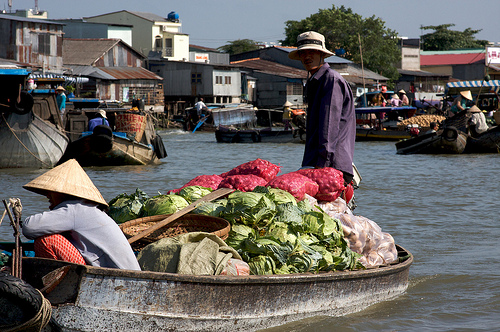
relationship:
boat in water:
[5, 237, 413, 331] [2, 129, 499, 331]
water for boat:
[2, 129, 499, 331] [5, 237, 413, 331]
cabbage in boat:
[228, 192, 271, 226] [5, 237, 413, 331]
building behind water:
[62, 38, 163, 128] [2, 129, 499, 331]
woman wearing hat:
[22, 156, 143, 273] [24, 158, 110, 208]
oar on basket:
[125, 185, 235, 243] [121, 212, 231, 249]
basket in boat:
[121, 212, 231, 249] [5, 237, 413, 331]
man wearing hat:
[290, 31, 356, 201] [289, 32, 334, 59]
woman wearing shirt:
[22, 156, 143, 273] [24, 200, 142, 270]